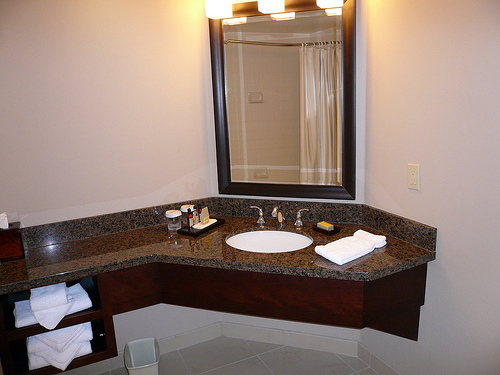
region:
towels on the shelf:
[13, 281, 97, 331]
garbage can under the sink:
[119, 334, 169, 374]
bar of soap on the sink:
[311, 215, 340, 237]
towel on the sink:
[317, 226, 393, 268]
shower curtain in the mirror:
[281, 33, 336, 183]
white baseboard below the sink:
[222, 320, 282, 344]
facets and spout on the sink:
[245, 203, 312, 232]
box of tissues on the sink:
[0, 208, 30, 264]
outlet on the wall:
[403, 154, 421, 194]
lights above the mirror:
[193, 0, 346, 18]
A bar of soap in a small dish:
[311, 216, 341, 237]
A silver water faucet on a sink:
[266, 198, 291, 231]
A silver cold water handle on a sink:
[289, 203, 313, 233]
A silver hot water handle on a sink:
[244, 201, 269, 227]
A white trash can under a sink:
[115, 330, 166, 374]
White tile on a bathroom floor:
[224, 344, 282, 368]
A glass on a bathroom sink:
[160, 204, 186, 235]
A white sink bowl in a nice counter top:
[223, 218, 314, 267]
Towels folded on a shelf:
[7, 278, 100, 336]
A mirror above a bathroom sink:
[204, 0, 360, 202]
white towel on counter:
[313, 229, 388, 265]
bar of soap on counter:
[318, 217, 335, 232]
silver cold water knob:
[295, 204, 310, 228]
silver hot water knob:
[252, 204, 269, 226]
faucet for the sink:
[271, 200, 292, 221]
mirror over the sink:
[221, 11, 355, 189]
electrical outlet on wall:
[407, 159, 418, 194]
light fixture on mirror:
[200, 2, 234, 19]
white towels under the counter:
[7, 283, 99, 332]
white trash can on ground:
[120, 332, 163, 374]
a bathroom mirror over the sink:
[213, 14, 360, 198]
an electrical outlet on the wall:
[405, 163, 420, 190]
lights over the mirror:
[204, 1, 349, 19]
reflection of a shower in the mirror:
[225, 29, 335, 184]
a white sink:
[229, 230, 309, 253]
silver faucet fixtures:
[250, 204, 307, 225]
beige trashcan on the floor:
[122, 335, 160, 372]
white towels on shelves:
[17, 291, 99, 370]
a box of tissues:
[0, 215, 23, 259]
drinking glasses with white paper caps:
[165, 203, 195, 230]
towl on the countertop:
[310, 205, 402, 290]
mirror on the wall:
[201, 13, 370, 213]